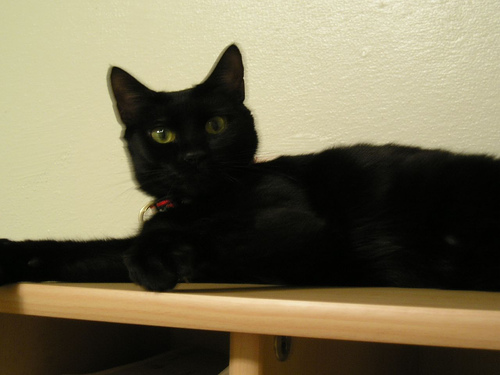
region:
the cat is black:
[79, 50, 498, 287]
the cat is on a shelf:
[0, 52, 493, 352]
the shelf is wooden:
[15, 267, 497, 374]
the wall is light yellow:
[6, 0, 498, 236]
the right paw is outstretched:
[0, 232, 146, 280]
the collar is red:
[148, 192, 176, 214]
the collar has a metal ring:
[132, 195, 159, 224]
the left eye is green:
[198, 112, 228, 137]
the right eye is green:
[144, 127, 177, 148]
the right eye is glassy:
[148, 123, 177, 147]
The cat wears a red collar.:
[138, 192, 182, 227]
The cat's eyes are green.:
[141, 112, 227, 144]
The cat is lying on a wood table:
[3, 254, 498, 349]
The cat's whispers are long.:
[113, 156, 270, 206]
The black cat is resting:
[7, 42, 497, 294]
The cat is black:
[6, 58, 498, 286]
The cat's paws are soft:
[0, 233, 203, 295]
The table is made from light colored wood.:
[8, 267, 498, 350]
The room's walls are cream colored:
[11, 9, 496, 244]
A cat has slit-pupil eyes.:
[143, 115, 228, 142]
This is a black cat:
[106, 73, 347, 326]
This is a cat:
[154, 115, 263, 353]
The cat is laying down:
[89, 156, 254, 363]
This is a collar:
[86, 191, 230, 259]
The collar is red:
[135, 198, 190, 260]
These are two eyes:
[89, 115, 271, 144]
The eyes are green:
[126, 94, 239, 174]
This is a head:
[80, 84, 321, 211]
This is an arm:
[64, 245, 165, 315]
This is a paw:
[113, 211, 212, 357]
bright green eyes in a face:
[144, 116, 243, 151]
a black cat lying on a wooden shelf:
[17, 42, 497, 347]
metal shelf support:
[269, 338, 300, 365]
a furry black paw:
[123, 247, 190, 294]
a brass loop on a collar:
[137, 203, 162, 218]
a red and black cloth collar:
[151, 193, 184, 217]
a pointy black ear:
[97, 56, 157, 123]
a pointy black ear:
[198, 43, 257, 102]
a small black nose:
[181, 140, 211, 165]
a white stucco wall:
[263, 13, 471, 130]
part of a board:
[443, 313, 466, 327]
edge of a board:
[325, 310, 339, 312]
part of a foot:
[161, 265, 175, 279]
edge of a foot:
[274, 230, 288, 265]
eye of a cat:
[221, 121, 233, 136]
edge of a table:
[287, 295, 294, 314]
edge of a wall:
[283, 307, 308, 344]